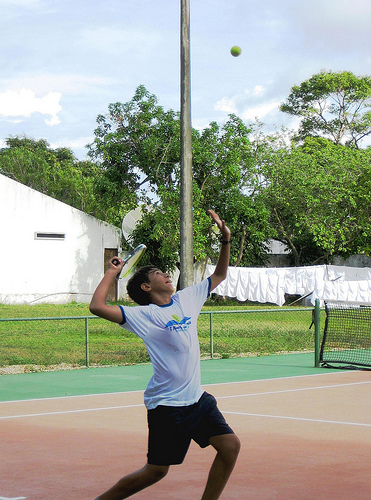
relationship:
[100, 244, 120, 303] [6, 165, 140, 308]
door on house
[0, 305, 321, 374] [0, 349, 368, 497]
fence surrounding court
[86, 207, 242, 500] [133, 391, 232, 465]
boy wearing shorts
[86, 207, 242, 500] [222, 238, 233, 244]
boy wearing black watch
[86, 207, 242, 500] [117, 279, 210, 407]
boy wearing shirt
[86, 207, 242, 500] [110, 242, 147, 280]
boy in mid swing with tennis racket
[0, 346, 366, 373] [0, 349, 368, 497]
dirt on boarder of court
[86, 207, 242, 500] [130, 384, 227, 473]
boy wearing shorts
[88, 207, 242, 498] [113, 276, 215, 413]
boy wearing shirt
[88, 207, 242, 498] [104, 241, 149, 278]
boy holding tennis racket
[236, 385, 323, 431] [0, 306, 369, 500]
lines painted on a court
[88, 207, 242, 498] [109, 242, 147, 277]
boy swinging a tennis racket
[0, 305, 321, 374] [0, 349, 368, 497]
fence on side of a court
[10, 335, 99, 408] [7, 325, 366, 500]
chain link fence lining ten court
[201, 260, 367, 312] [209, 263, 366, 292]
clothes hanging on clothes line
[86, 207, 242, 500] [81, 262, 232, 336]
boy player looking upward